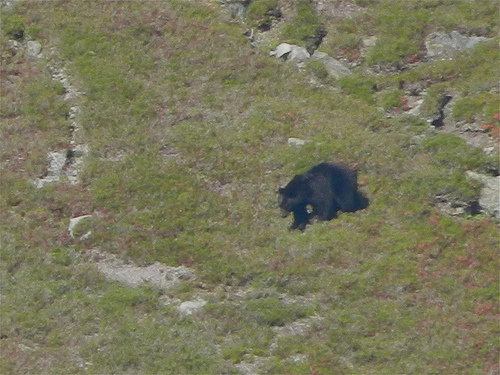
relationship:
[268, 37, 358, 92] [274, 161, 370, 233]
rocks behind bear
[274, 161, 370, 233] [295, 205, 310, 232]
bear has leg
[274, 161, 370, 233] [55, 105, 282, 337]
bear in middle of field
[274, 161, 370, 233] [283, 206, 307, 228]
bear has leg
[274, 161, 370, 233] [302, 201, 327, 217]
bear has leg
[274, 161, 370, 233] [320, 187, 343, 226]
bear has leg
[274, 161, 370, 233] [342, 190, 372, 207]
bear has leg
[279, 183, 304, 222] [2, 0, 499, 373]
head towards ground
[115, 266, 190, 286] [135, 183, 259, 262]
gravel in grass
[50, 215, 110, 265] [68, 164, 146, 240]
rock in ground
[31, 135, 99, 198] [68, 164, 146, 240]
gravel in ground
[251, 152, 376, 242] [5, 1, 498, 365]
bear on grass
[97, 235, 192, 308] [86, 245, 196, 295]
rock of dirt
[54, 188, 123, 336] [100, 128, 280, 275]
rock in grass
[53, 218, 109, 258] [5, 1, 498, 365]
rock growing on grass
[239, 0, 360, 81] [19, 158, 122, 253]
rocks on ground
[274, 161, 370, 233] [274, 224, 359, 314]
bear walking on grass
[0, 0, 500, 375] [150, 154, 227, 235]
ground of a ground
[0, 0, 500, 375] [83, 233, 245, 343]
ground of a ground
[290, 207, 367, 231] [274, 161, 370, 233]
edge of a bear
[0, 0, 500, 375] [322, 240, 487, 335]
ground of a ground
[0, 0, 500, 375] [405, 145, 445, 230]
ground of a ground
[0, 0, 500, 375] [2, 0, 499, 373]
ground of a ground